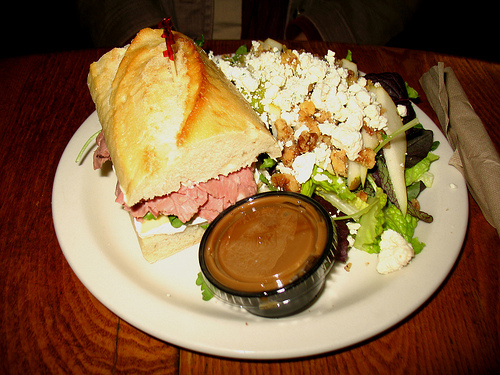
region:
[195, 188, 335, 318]
Black plastic condiment container with clear lid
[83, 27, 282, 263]
Sandwich on a white plate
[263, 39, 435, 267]
Salad on a white plate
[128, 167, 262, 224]
Meat in a sandwich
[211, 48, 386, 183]
Salad with feta next to a sandwich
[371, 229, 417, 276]
Feta cheese next to lettuce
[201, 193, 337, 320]
Cup of sauce on a plate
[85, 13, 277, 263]
Half a sandwich on a plate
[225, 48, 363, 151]
Cheese clumps on a salad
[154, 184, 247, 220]
Meat inside a sandwich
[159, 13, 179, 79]
Toothpick with red plastic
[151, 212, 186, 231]
Green lettuce on a sandwich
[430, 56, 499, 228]
Rolled napkin beside a plate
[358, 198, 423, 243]
Lettuce in a salad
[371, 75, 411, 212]
Cheese on a salad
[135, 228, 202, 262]
Bottom slice of bread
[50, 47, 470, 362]
a white plate filled with food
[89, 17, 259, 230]
a hoagie sandwich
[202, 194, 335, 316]
a plastic container with dressing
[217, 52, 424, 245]
a salad on a plate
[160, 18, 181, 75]
a toothpick holding the sandwich together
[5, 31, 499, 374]
a brown wooden table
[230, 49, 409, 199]
cheese and nuts on a bed of lettuce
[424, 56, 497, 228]
a brown rolled paper napkin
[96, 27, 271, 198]
top slice of bread on the sandwich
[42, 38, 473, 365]
a round white plate on a table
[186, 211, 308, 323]
brown sauce in cup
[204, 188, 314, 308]
small black plastic cup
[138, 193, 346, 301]
plastic lid on cup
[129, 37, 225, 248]
light brown bread on sandwich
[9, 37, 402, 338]
sandwich on white plate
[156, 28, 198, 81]
red wrapper on toothpick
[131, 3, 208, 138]
toothpick inserted in sandwich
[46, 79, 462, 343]
white and round plate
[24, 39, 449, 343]
plate on wooden table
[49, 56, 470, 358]
white plate on top of a wooden table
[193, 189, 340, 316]
black plastic cup on top of plate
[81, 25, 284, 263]
sandwich on top of plate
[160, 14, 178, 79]
decorative toothpick inserted into sandwich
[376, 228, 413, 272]
white feta cheese on top of plate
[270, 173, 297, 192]
walnut on top of salad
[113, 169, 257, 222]
meat inside sandwich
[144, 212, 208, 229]
green lettuce under meat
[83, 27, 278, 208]
bread on top of meat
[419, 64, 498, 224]
paper napkin to the right of the plate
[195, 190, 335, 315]
A black container with a clear lid.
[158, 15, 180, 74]
A toothpick in the sandwich.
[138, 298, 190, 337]
The edge of the plate.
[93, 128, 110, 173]
Meat hanging out of the sandwich.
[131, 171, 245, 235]
meat in the sandwich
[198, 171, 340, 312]
brown gravy in container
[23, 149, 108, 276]
edge of the plate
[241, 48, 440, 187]
food next to sandwich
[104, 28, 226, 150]
brown and white bun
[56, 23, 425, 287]
many items of food on plate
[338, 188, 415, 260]
green food on plate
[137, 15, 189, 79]
toothpick in the food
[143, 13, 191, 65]
red tip of the item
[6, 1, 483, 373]
a scene inside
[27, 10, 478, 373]
a person is about to eat this